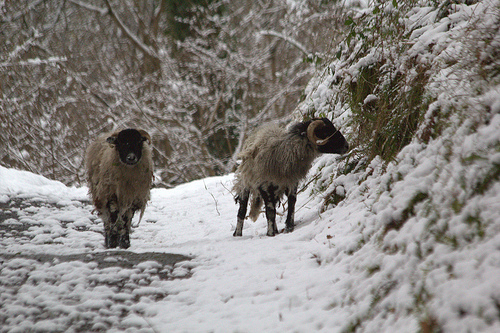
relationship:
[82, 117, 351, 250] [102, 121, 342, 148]
sheep have horns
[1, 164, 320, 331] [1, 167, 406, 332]
ground has snow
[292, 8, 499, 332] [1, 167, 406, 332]
hill has snow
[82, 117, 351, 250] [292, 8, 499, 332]
sheep are sniffing hill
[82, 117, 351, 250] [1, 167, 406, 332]
sheep are walking in snow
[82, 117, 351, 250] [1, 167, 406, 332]
sheep are on snow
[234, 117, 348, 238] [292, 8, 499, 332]
ram looking at hill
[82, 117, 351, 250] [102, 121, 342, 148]
sheep has horns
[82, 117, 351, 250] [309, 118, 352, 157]
sheep has fur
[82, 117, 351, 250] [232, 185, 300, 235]
sheep has legs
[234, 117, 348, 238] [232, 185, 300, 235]
ram has legs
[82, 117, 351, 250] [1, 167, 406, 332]
sheep are i snow